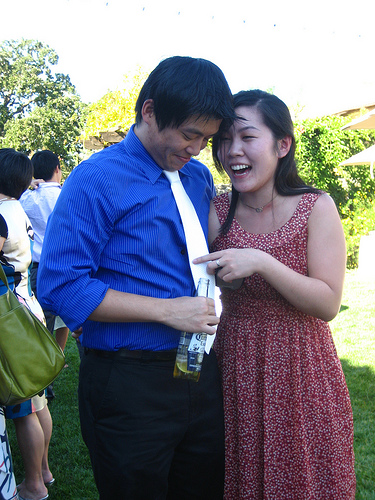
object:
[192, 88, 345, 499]
people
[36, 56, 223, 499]
man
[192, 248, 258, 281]
hand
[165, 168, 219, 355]
tie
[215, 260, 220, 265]
ring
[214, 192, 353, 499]
dress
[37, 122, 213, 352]
shirt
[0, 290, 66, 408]
purse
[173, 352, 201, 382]
beer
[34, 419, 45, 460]
calf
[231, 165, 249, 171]
teeth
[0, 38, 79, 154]
leaves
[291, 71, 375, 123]
roof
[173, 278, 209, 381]
bottle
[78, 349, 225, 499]
pants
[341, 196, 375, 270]
bushes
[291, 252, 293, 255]
dots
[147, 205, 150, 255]
stripes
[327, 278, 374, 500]
grass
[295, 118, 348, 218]
tree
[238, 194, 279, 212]
necklace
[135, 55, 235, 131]
hair